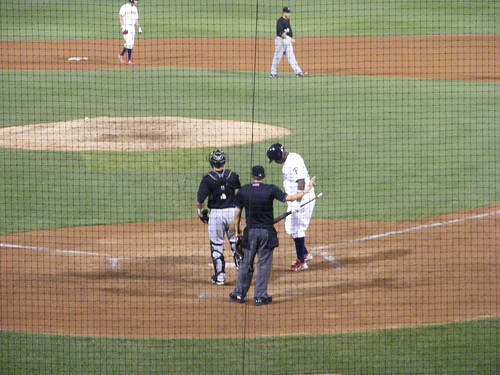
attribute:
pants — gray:
[206, 206, 238, 286]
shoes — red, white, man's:
[288, 251, 312, 282]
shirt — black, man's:
[235, 182, 285, 227]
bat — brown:
[266, 191, 323, 222]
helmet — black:
[251, 134, 298, 166]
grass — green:
[0, 1, 497, 373]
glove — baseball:
[116, 26, 129, 36]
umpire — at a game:
[230, 163, 315, 303]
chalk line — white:
[316, 209, 498, 249]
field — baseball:
[0, 0, 498, 373]